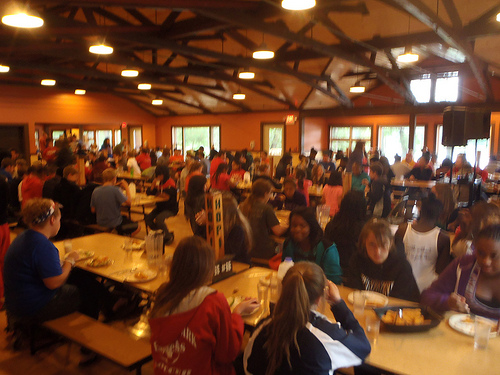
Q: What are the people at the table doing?
A: Sitting.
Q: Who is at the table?
A: Woman and men.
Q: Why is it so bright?
A: The lights are on.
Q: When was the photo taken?
A: Day time.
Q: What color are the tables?
A: White.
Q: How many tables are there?
A: A dozen.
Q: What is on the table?
A: Cups and plates.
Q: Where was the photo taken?
A: In a dining hall.